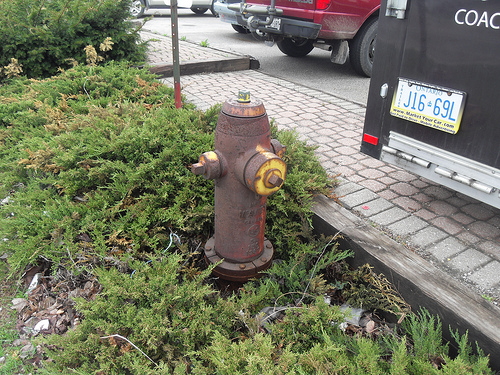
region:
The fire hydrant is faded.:
[179, 80, 291, 283]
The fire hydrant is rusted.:
[189, 83, 282, 298]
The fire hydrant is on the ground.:
[158, 75, 298, 311]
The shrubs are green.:
[28, 89, 169, 268]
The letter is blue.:
[401, 90, 414, 117]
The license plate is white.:
[389, 72, 471, 129]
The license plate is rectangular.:
[389, 65, 475, 139]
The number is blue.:
[433, 95, 441, 119]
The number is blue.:
[439, 98, 451, 120]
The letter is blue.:
[447, 95, 462, 130]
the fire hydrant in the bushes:
[188, 77, 300, 297]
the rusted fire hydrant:
[190, 83, 294, 281]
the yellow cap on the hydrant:
[246, 149, 288, 196]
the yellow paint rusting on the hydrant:
[247, 143, 287, 200]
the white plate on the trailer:
[393, 80, 468, 137]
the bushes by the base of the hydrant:
[0, 255, 405, 368]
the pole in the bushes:
[156, 0, 186, 113]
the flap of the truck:
[328, 35, 350, 72]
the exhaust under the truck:
[311, 39, 331, 54]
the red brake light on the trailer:
[359, 128, 377, 151]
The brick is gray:
[325, 176, 367, 198]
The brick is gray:
[351, 200, 394, 215]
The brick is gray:
[392, 209, 416, 237]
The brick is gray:
[430, 235, 463, 261]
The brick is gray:
[449, 245, 486, 275]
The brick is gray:
[470, 266, 498, 293]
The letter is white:
[449, 3, 469, 33]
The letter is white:
[465, 3, 478, 31]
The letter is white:
[477, 10, 491, 31]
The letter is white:
[488, 8, 499, 33]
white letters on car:
[447, 3, 497, 33]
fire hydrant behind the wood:
[195, 91, 285, 288]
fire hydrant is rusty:
[191, 86, 286, 283]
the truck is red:
[242, 1, 380, 77]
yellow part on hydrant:
[250, 159, 285, 195]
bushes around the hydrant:
[5, 60, 499, 372]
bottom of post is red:
[171, 79, 184, 109]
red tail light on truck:
[313, 1, 335, 16]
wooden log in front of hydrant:
[303, 189, 498, 361]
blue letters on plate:
[398, 84, 457, 122]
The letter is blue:
[400, 85, 415, 112]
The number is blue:
[409, 83, 421, 116]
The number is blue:
[415, 88, 426, 119]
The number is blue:
[430, 92, 443, 129]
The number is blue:
[436, 90, 451, 129]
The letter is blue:
[448, 96, 461, 131]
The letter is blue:
[412, 76, 422, 96]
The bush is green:
[25, 116, 328, 240]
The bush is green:
[2, 59, 186, 143]